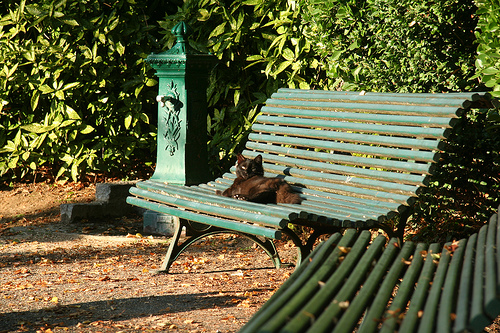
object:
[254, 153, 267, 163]
ear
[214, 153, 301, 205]
cat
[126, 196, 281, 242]
board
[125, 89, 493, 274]
bench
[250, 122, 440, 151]
board